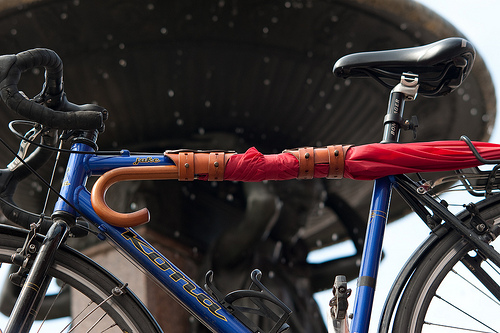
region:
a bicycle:
[2, 7, 494, 331]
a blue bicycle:
[5, 33, 494, 322]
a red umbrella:
[84, 134, 499, 224]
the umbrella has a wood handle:
[88, 131, 495, 264]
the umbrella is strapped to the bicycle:
[75, 127, 496, 236]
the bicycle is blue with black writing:
[3, 26, 498, 323]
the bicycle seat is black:
[325, 25, 481, 112]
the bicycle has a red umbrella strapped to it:
[4, 41, 496, 332]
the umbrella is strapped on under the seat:
[51, 125, 496, 260]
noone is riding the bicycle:
[1, 11, 486, 332]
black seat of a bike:
[319, 23, 478, 95]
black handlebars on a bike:
[0, 45, 111, 142]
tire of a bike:
[0, 203, 172, 330]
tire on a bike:
[377, 185, 499, 331]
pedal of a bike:
[322, 254, 357, 331]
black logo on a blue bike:
[109, 219, 234, 326]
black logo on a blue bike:
[128, 151, 164, 168]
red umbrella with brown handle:
[79, 132, 499, 231]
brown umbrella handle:
[71, 160, 190, 237]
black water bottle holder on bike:
[196, 255, 298, 332]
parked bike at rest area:
[2, 33, 497, 326]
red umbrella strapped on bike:
[86, 135, 496, 225]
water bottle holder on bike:
[200, 265, 291, 330]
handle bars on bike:
[0, 41, 105, 126]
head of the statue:
[265, 180, 325, 240]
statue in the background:
[195, 180, 365, 330]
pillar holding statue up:
[70, 245, 190, 330]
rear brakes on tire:
[465, 195, 495, 255]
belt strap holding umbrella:
[176, 149, 226, 184]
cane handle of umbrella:
[89, 162, 179, 227]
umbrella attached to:
[85, 130, 475, 261]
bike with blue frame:
[44, 121, 401, 320]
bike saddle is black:
[328, 26, 490, 121]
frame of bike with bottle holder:
[186, 257, 308, 332]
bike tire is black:
[394, 203, 495, 331]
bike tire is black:
[0, 226, 152, 331]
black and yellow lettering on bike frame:
[108, 208, 251, 324]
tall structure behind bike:
[0, 6, 491, 273]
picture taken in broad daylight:
[0, 5, 496, 328]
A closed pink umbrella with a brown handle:
[86, 144, 499, 227]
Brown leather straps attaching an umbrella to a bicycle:
[38, 140, 498, 225]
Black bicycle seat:
[324, 35, 481, 130]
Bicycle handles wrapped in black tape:
[0, 37, 115, 238]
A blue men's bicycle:
[5, 20, 495, 317]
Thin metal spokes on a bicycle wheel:
[391, 260, 496, 330]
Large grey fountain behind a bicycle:
[3, 3, 496, 322]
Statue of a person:
[186, 125, 402, 330]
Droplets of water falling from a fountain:
[156, 16, 499, 163]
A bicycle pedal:
[320, 269, 362, 331]